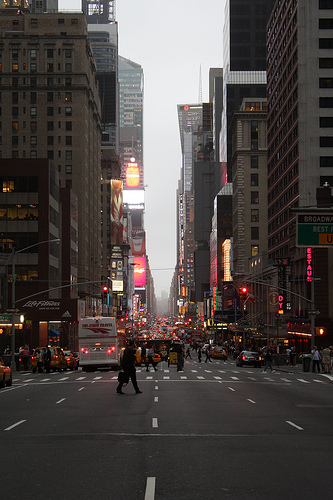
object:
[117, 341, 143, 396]
guy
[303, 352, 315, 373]
garbage can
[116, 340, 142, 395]
person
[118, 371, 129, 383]
bag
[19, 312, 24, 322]
light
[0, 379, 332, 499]
four lane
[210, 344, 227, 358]
yellow taxi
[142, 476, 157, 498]
lines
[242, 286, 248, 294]
street light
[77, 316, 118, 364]
bus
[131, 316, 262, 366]
traffic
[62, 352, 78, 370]
taxi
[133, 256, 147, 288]
sign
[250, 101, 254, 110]
window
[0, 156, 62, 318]
building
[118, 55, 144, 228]
building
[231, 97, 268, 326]
building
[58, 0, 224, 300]
sky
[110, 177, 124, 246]
billboards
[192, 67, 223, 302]
buildings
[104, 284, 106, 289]
traffic lights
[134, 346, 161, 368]
taxi cab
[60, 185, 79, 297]
building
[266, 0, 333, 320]
building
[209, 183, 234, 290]
building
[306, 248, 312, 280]
sign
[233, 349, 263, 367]
car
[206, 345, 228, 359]
car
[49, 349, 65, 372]
car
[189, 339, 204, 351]
car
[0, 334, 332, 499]
street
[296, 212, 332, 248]
sign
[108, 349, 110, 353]
tail light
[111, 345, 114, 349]
tail light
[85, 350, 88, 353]
tail light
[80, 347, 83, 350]
tail light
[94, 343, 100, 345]
tail light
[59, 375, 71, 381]
white marks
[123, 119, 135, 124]
window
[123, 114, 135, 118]
window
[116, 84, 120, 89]
window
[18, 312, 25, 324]
traffic signal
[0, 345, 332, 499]
roadway